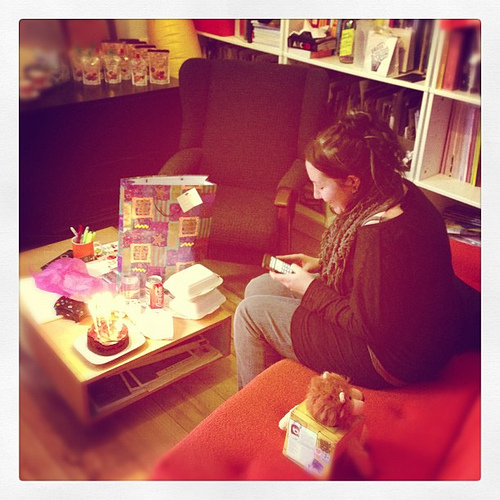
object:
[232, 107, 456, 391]
woman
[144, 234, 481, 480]
couch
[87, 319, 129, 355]
cake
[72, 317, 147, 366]
plate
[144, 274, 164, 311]
can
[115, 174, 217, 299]
gift bag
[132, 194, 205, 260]
print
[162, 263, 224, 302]
container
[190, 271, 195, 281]
white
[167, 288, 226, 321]
container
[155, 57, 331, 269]
chair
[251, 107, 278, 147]
brown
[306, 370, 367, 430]
lion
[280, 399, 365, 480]
box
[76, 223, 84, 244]
pens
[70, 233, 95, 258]
cup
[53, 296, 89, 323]
controller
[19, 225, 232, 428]
table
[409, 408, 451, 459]
red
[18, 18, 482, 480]
room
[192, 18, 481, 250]
bookshelf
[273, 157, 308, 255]
arm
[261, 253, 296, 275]
phone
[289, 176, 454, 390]
shirt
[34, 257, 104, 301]
paper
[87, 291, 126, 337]
candles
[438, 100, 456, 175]
books